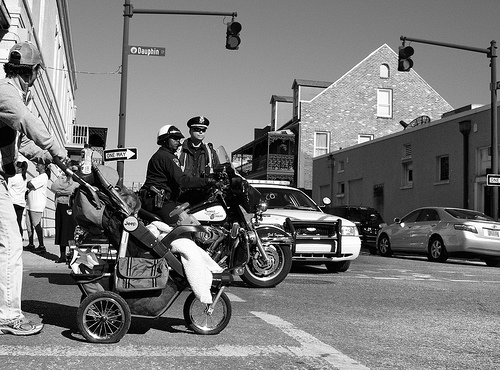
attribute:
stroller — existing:
[43, 144, 240, 346]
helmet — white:
[151, 123, 186, 147]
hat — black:
[186, 113, 215, 129]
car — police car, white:
[238, 174, 360, 275]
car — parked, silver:
[374, 203, 499, 264]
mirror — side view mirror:
[315, 193, 334, 213]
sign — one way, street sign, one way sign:
[99, 144, 143, 165]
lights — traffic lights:
[221, 10, 243, 56]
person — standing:
[0, 40, 74, 342]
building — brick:
[289, 43, 463, 196]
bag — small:
[107, 250, 173, 296]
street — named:
[0, 207, 497, 369]